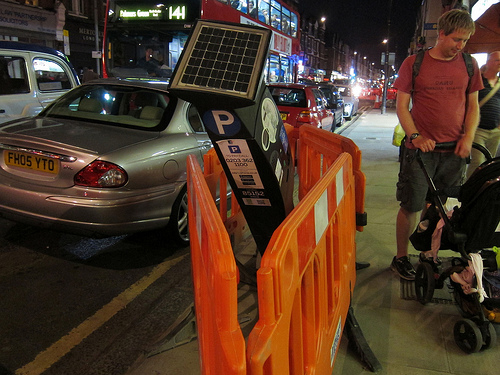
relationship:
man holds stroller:
[399, 23, 474, 279] [431, 152, 499, 354]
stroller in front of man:
[431, 152, 499, 354] [399, 23, 474, 279]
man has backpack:
[399, 23, 474, 279] [418, 51, 470, 90]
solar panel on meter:
[190, 18, 265, 106] [148, 17, 295, 244]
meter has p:
[148, 17, 295, 244] [209, 108, 240, 145]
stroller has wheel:
[431, 152, 499, 354] [413, 258, 436, 302]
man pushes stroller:
[399, 23, 474, 279] [431, 152, 499, 354]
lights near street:
[329, 72, 375, 94] [1, 92, 359, 371]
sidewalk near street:
[325, 97, 499, 370] [1, 92, 359, 371]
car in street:
[14, 75, 205, 257] [1, 92, 359, 371]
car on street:
[14, 75, 205, 257] [1, 92, 359, 371]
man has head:
[399, 23, 474, 279] [437, 7, 473, 59]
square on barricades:
[297, 204, 336, 236] [159, 117, 381, 374]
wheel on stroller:
[413, 258, 436, 302] [431, 152, 499, 354]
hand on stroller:
[413, 134, 440, 157] [431, 152, 499, 354]